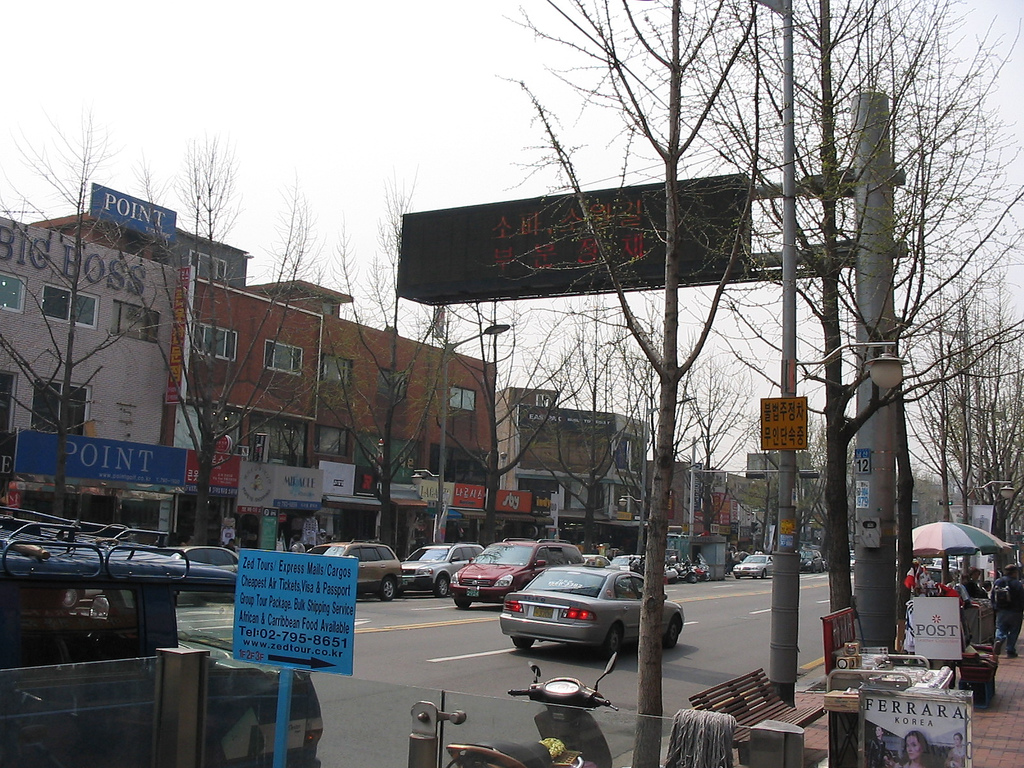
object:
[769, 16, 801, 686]
pole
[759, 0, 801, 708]
light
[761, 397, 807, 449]
sign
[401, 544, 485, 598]
van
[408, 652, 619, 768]
moped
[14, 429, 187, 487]
blue sign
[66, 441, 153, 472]
point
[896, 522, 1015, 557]
umbrella